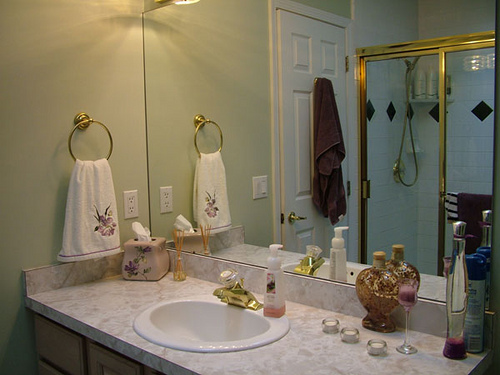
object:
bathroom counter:
[17, 249, 493, 371]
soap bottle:
[264, 240, 288, 320]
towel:
[61, 158, 124, 265]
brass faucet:
[214, 267, 264, 312]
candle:
[400, 284, 416, 304]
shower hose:
[392, 73, 419, 188]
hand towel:
[56, 159, 126, 264]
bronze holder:
[66, 110, 114, 159]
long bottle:
[441, 219, 477, 359]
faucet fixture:
[210, 268, 264, 312]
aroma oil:
[168, 225, 189, 283]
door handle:
[288, 210, 308, 229]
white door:
[268, 2, 380, 261]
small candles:
[366, 338, 391, 357]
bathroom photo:
[0, 0, 499, 375]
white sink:
[133, 290, 292, 356]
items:
[120, 219, 487, 361]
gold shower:
[353, 30, 500, 279]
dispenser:
[121, 238, 171, 281]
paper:
[130, 218, 158, 247]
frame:
[356, 30, 499, 279]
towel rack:
[65, 114, 114, 167]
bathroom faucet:
[209, 265, 262, 313]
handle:
[218, 268, 243, 288]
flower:
[91, 201, 118, 237]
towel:
[308, 76, 348, 227]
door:
[262, 3, 365, 265]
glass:
[396, 276, 419, 356]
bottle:
[259, 239, 293, 324]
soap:
[264, 302, 289, 317]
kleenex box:
[121, 237, 171, 284]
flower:
[124, 253, 147, 282]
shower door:
[348, 28, 500, 280]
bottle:
[441, 215, 470, 361]